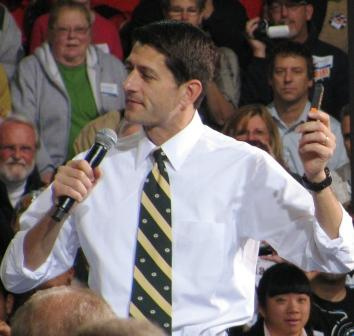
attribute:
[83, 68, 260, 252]
man — white, striped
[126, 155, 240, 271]
shirt — white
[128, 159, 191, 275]
tie — black, striped, yellow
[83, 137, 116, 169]
microphone — black